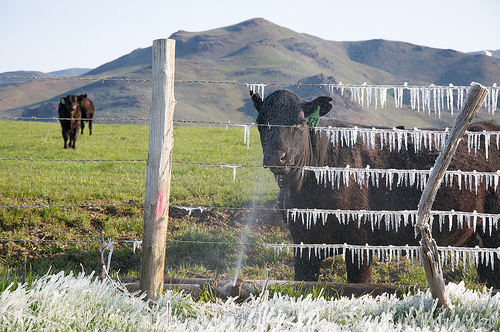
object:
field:
[3, 120, 253, 279]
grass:
[11, 278, 122, 330]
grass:
[6, 124, 30, 155]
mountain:
[1, 15, 499, 127]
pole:
[137, 37, 172, 300]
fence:
[0, 71, 499, 302]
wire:
[1, 239, 133, 244]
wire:
[0, 204, 144, 208]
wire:
[1, 158, 146, 162]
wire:
[0, 74, 149, 82]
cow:
[58, 93, 82, 150]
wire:
[0, 116, 148, 120]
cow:
[77, 93, 95, 136]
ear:
[250, 90, 263, 113]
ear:
[60, 97, 67, 103]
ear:
[85, 93, 88, 99]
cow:
[247, 90, 500, 291]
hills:
[0, 17, 500, 126]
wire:
[173, 119, 293, 129]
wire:
[172, 160, 299, 169]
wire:
[166, 206, 286, 212]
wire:
[163, 239, 263, 247]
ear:
[305, 96, 333, 118]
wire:
[173, 80, 318, 87]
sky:
[27, 15, 87, 57]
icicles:
[331, 82, 499, 119]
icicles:
[314, 125, 498, 162]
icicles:
[300, 164, 499, 196]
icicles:
[285, 209, 497, 233]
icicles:
[262, 243, 498, 272]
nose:
[264, 150, 287, 162]